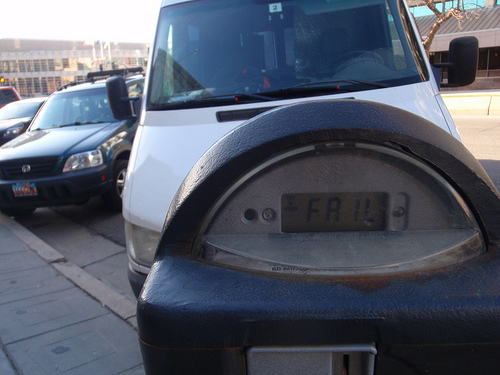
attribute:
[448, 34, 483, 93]
mirror — BLACK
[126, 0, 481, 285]
van — WHITE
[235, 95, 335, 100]
wiper — black 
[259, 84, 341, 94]
wiper — black 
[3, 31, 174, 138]
building — brown 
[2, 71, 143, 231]
truck — BLUE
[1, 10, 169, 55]
sky — GREY, BRIGHT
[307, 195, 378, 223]
letters — BLACK